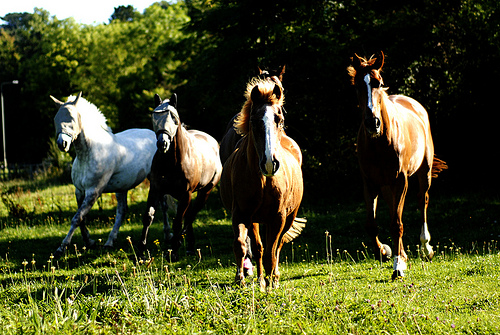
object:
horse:
[216, 63, 305, 291]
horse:
[345, 48, 447, 283]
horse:
[45, 91, 159, 256]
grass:
[2, 178, 499, 333]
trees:
[1, 7, 121, 154]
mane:
[231, 72, 284, 137]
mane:
[347, 52, 385, 85]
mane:
[65, 94, 112, 133]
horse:
[136, 91, 223, 258]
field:
[0, 2, 499, 333]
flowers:
[129, 265, 137, 273]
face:
[250, 104, 281, 176]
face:
[151, 105, 175, 152]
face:
[353, 68, 386, 136]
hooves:
[232, 273, 245, 286]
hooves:
[52, 246, 66, 260]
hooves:
[388, 264, 404, 282]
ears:
[250, 84, 263, 100]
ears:
[349, 53, 365, 67]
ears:
[70, 89, 84, 105]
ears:
[170, 92, 179, 107]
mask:
[150, 108, 177, 143]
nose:
[258, 155, 280, 179]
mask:
[50, 105, 83, 138]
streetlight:
[0, 79, 20, 178]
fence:
[0, 163, 39, 182]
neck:
[240, 111, 261, 167]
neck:
[380, 87, 393, 140]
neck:
[73, 118, 108, 154]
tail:
[283, 215, 308, 245]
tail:
[430, 157, 448, 182]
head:
[248, 84, 284, 177]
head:
[347, 50, 385, 138]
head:
[47, 90, 85, 153]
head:
[150, 91, 181, 156]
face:
[50, 107, 74, 145]